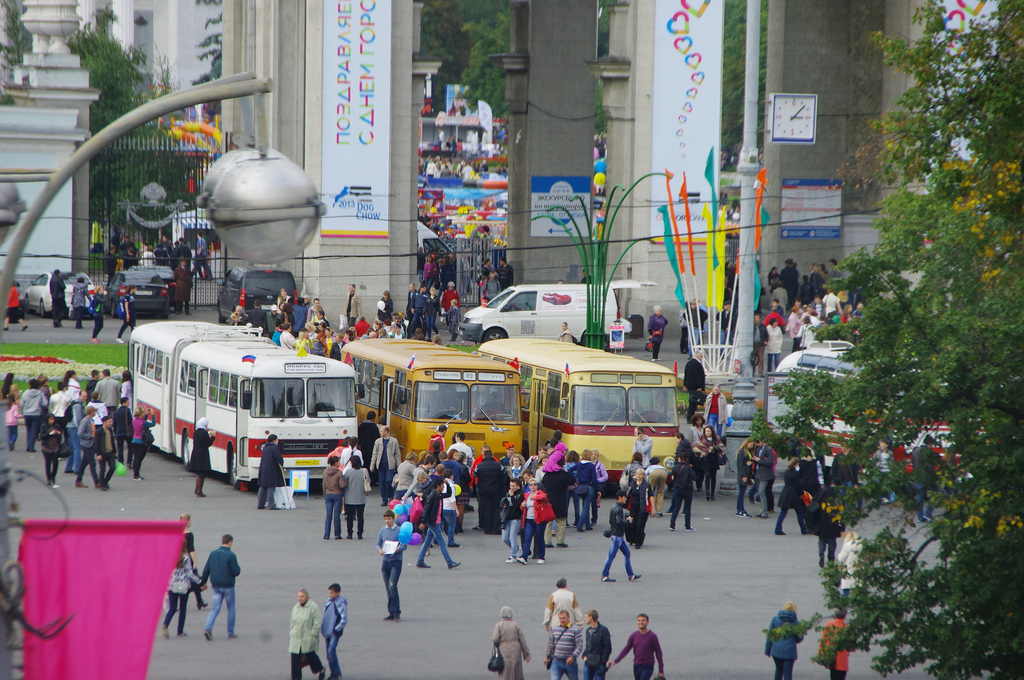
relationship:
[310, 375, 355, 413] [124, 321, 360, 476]
window on bus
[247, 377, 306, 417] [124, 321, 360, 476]
window on bus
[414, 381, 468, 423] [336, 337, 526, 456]
window on bus